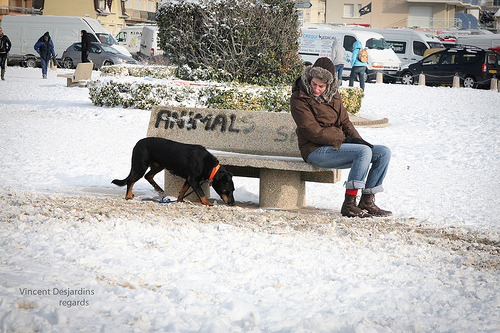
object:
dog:
[110, 136, 238, 208]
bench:
[142, 99, 343, 213]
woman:
[286, 56, 394, 221]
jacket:
[287, 55, 376, 165]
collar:
[207, 161, 223, 184]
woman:
[345, 39, 371, 94]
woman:
[328, 36, 349, 88]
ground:
[1, 226, 498, 332]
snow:
[391, 91, 498, 201]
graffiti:
[153, 108, 262, 135]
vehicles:
[56, 40, 138, 73]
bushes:
[85, 62, 368, 118]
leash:
[139, 176, 209, 204]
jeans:
[304, 138, 394, 196]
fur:
[300, 63, 340, 105]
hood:
[297, 55, 344, 105]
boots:
[338, 191, 374, 220]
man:
[31, 29, 58, 80]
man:
[0, 26, 14, 82]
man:
[76, 28, 99, 71]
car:
[392, 42, 500, 94]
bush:
[151, 0, 305, 87]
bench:
[54, 60, 95, 88]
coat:
[350, 40, 369, 68]